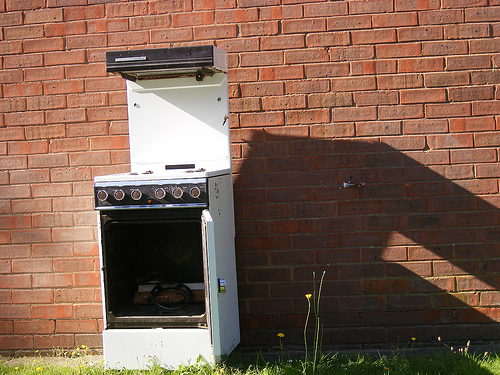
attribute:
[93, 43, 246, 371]
oven — doorless, dark inside, white, broken down, old, sitting, odd, alone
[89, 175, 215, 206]
dials — black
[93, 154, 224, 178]
stove — white, black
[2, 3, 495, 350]
wall — brick, red, dark, light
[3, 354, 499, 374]
grass — green, small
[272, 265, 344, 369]
dandelions — tall, growing, weeds, flowered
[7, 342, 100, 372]
flower — yellow